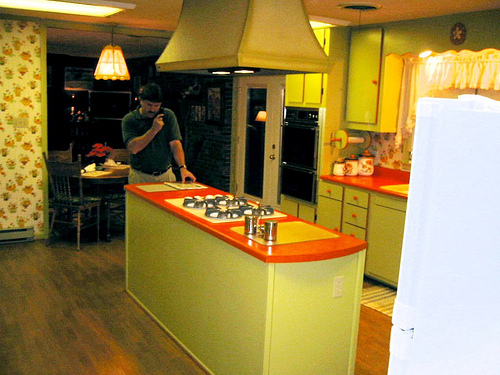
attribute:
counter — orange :
[319, 165, 410, 187]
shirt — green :
[120, 105, 182, 175]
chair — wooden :
[16, 129, 136, 271]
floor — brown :
[5, 233, 172, 372]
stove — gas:
[166, 190, 288, 225]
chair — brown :
[35, 146, 111, 256]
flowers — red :
[81, 129, 124, 194]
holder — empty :
[328, 127, 373, 151]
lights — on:
[96, 46, 128, 85]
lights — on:
[207, 66, 259, 81]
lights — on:
[254, 105, 264, 122]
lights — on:
[305, 5, 347, 39]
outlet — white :
[329, 266, 349, 302]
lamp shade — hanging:
[94, 42, 131, 82]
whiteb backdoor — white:
[233, 70, 285, 207]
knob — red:
[346, 191, 363, 224]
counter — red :
[324, 163, 421, 201]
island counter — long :
[123, 181, 368, 373]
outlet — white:
[326, 273, 351, 303]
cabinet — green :
[343, 20, 381, 133]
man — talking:
[117, 83, 194, 190]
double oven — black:
[280, 107, 315, 200]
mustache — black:
[138, 108, 157, 116]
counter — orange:
[127, 184, 370, 264]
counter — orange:
[325, 157, 415, 205]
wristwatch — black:
[175, 160, 187, 170]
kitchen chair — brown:
[37, 149, 105, 241]